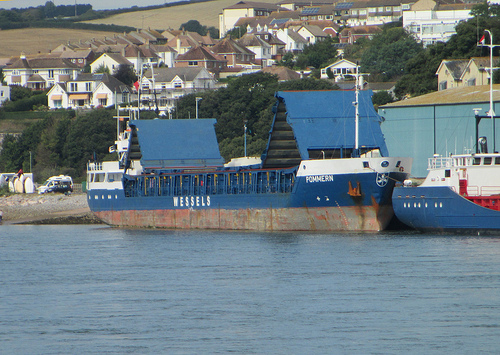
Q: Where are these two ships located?
A: A large body of water.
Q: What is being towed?
A: A small boat.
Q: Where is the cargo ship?
A: On the water.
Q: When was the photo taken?
A: Daylight hours.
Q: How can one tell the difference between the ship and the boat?
A: The ship is larger than the boat.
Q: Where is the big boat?
A: In the harbor.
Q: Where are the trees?
A: They are on the land.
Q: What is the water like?
A: Wavy.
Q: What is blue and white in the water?
A: The ship.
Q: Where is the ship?
A: In the water.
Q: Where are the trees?
A: Between the houses.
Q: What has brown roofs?
A: The houses.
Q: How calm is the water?
A: Very calm.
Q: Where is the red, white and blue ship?
A: Right side.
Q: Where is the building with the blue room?
A: On the shore.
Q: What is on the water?
A: Boat.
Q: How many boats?
A: 2.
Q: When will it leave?
A: Soon.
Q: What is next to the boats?
A: Trees.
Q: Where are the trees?
A: On land.